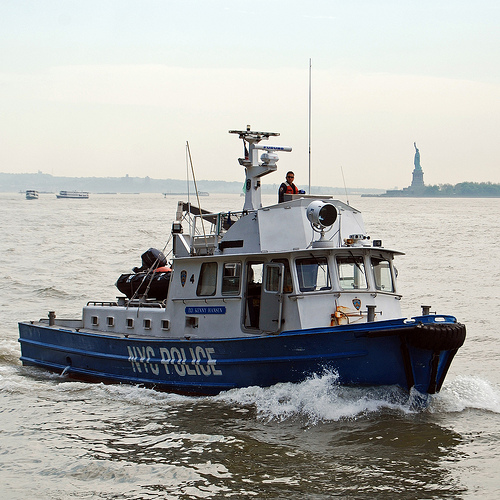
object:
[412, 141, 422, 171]
statue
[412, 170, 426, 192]
pedestal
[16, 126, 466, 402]
boat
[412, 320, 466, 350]
tire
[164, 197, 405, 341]
cabin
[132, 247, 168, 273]
motor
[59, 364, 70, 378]
water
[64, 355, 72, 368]
hole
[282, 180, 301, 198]
vest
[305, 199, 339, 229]
light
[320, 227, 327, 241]
pole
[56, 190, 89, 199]
boat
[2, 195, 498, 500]
sea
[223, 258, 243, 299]
window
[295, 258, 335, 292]
window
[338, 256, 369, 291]
window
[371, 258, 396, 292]
window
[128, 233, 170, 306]
rope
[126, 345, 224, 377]
sign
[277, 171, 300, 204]
officer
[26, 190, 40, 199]
ferry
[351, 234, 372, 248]
horn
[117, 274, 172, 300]
raft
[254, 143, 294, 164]
radar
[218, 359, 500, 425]
wave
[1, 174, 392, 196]
skyline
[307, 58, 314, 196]
aentenna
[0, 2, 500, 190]
sky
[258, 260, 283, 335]
door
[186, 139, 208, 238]
pole